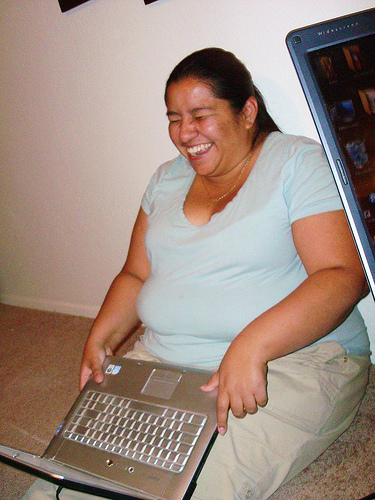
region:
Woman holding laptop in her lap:
[111, 125, 339, 440]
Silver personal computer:
[17, 351, 207, 498]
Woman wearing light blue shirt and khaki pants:
[118, 186, 351, 439]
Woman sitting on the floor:
[75, 287, 358, 452]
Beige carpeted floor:
[2, 302, 79, 378]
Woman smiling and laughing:
[142, 79, 246, 211]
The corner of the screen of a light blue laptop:
[276, 16, 365, 200]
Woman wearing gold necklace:
[161, 149, 264, 195]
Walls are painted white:
[23, 34, 157, 181]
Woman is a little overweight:
[109, 247, 294, 342]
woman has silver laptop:
[45, 356, 220, 495]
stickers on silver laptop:
[97, 359, 132, 387]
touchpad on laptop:
[141, 370, 178, 401]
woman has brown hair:
[160, 53, 284, 162]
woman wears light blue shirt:
[106, 121, 341, 336]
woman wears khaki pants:
[215, 323, 343, 494]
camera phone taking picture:
[295, 45, 373, 199]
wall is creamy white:
[1, 35, 101, 261]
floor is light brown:
[12, 308, 60, 437]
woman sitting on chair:
[283, 412, 373, 489]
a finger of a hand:
[210, 390, 232, 436]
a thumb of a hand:
[87, 351, 107, 388]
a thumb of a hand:
[199, 373, 223, 397]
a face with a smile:
[163, 91, 217, 161]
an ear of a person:
[241, 91, 260, 133]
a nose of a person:
[176, 121, 199, 145]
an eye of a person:
[186, 106, 220, 125]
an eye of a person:
[166, 108, 182, 128]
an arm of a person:
[251, 270, 364, 369]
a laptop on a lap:
[30, 361, 236, 497]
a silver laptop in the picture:
[0, 353, 233, 496]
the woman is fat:
[6, 45, 373, 499]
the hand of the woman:
[199, 170, 359, 440]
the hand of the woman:
[69, 203, 159, 385]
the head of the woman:
[160, 46, 275, 182]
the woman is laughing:
[162, 77, 243, 173]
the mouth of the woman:
[181, 142, 224, 167]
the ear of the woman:
[238, 97, 263, 127]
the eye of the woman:
[191, 106, 226, 128]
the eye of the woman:
[160, 108, 183, 129]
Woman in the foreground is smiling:
[164, 99, 236, 173]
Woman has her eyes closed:
[159, 96, 233, 137]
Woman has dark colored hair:
[159, 45, 281, 151]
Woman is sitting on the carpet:
[60, 279, 373, 456]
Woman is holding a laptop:
[3, 349, 303, 494]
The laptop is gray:
[0, 349, 248, 496]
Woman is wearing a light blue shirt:
[112, 124, 372, 368]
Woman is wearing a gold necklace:
[190, 151, 261, 205]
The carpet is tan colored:
[2, 308, 371, 497]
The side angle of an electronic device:
[269, 0, 373, 308]